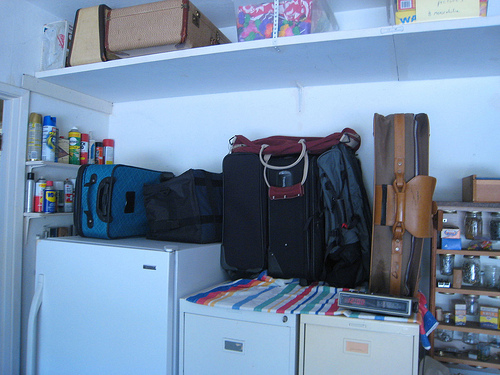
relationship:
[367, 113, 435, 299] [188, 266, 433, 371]
suitcase on file cabinet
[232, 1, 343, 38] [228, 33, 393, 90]
clothes on shelf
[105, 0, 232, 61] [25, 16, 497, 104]
suitcase on shelf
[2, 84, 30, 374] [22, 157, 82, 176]
door frame next to shelf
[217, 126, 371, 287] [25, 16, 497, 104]
suitcase under shelf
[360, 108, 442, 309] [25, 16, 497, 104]
suitcase under shelf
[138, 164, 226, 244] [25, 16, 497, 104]
suitcase under shelf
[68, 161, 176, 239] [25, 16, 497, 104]
suitcase under shelf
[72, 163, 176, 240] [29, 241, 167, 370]
suitcase on top of refrigerator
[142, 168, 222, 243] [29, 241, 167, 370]
suitcase on top of refrigerator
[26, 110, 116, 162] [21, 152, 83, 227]
cans sitting on shelf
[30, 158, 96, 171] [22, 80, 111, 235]
shelf built into wall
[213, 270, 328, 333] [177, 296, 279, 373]
blanket on top of cabinet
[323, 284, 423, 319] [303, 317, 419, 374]
alarm clock on top of cabinet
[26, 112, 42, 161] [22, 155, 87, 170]
can on shelf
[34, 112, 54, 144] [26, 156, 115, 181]
can on shelf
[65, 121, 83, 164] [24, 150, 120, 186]
can on shelf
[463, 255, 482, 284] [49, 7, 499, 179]
jar on shelf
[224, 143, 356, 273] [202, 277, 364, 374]
suitcase on top of filing cabinet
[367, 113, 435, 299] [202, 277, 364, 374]
suitcase on top of filing cabinet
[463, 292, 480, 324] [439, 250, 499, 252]
jar on shelf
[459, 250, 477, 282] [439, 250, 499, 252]
jar on shelf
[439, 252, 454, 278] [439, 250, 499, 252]
jar on shelf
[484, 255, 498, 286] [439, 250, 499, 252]
jar on shelf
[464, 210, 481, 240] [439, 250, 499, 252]
jar on shelf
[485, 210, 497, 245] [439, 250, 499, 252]
jar on shelf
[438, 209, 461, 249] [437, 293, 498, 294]
jar on shelf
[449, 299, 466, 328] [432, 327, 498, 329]
jar on shelf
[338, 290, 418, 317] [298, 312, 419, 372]
clock on file cabinet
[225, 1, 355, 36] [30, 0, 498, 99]
storage bin sitting on top shelf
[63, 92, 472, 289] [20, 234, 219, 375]
suitcases on fridge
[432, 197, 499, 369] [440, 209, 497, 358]
shelf with supplies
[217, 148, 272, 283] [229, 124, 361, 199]
suit case with a bag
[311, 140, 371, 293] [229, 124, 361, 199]
suit case with a bag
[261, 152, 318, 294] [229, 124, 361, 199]
suit case with a bag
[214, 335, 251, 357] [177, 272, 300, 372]
handle on cabinet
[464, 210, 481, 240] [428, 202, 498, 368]
trinket sitting in a shelf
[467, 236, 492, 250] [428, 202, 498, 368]
trinket sitting in a shelf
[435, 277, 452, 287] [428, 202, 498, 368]
trinket sitting in a shelf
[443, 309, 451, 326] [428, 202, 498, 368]
trinket sitting in a shelf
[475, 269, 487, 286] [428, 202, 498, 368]
trinket sitting in a shelf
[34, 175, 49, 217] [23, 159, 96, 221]
can on shelf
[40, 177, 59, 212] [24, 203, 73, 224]
can on shelf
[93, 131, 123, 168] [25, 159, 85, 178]
can shelf on shelf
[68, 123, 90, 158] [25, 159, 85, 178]
can shelf on shelf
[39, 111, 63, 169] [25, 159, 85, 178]
can shelf on shelf